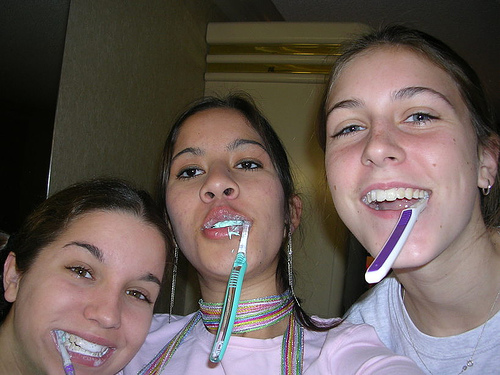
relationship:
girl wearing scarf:
[114, 89, 426, 374] [138, 287, 306, 373]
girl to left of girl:
[3, 180, 170, 374] [153, 83, 301, 360]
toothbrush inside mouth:
[359, 191, 429, 288] [353, 175, 433, 219]